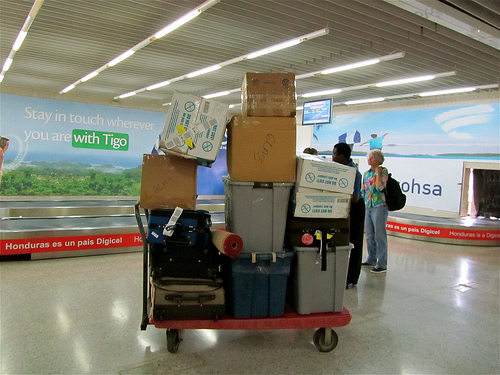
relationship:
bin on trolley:
[224, 176, 294, 253] [134, 200, 351, 352]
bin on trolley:
[231, 252, 294, 319] [134, 200, 351, 352]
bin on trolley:
[296, 244, 352, 315] [134, 200, 351, 352]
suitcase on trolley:
[147, 207, 211, 245] [134, 200, 351, 352]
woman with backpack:
[360, 149, 388, 273] [385, 173, 407, 211]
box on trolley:
[140, 154, 197, 208] [134, 200, 351, 352]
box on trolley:
[158, 90, 229, 168] [134, 200, 351, 352]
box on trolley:
[228, 116, 297, 184] [134, 200, 351, 352]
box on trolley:
[241, 72, 296, 117] [134, 200, 351, 352]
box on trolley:
[293, 154, 357, 218] [134, 200, 351, 352]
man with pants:
[332, 142, 365, 291] [350, 197, 367, 289]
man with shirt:
[332, 142, 365, 291] [340, 161, 363, 197]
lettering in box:
[73, 132, 128, 149] [72, 127, 130, 151]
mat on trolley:
[207, 227, 244, 257] [134, 200, 351, 352]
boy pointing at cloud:
[360, 132, 390, 150] [434, 104, 494, 122]